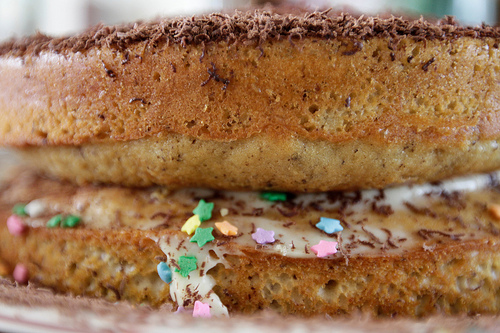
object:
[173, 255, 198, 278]
sprinkles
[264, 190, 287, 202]
star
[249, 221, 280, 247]
sprinkle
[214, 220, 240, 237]
sprinkles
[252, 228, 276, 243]
sprinkles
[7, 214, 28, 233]
sprinkles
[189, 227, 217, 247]
sprinkles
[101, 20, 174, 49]
shavings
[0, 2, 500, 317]
pancake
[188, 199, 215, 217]
sprinkle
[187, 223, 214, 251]
sprinkle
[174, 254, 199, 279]
sprinkle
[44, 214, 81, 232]
sprinkle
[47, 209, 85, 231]
sprinkle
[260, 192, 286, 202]
sprinkle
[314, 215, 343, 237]
sprinkle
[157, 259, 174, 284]
sprinkle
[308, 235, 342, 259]
sprinkle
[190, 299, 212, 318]
sprinkle